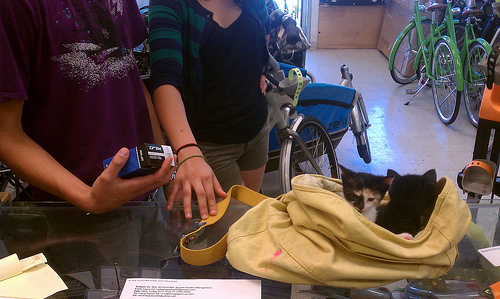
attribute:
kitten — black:
[340, 164, 383, 215]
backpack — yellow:
[293, 235, 457, 271]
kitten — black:
[392, 175, 433, 206]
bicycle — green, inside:
[409, 11, 436, 53]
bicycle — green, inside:
[466, 29, 482, 43]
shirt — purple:
[55, 107, 76, 127]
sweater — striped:
[158, 13, 188, 58]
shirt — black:
[243, 19, 253, 32]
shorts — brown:
[211, 148, 267, 171]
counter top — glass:
[12, 217, 168, 254]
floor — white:
[377, 103, 426, 157]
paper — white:
[14, 258, 54, 298]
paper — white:
[130, 284, 252, 298]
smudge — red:
[270, 245, 289, 259]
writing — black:
[165, 289, 189, 292]